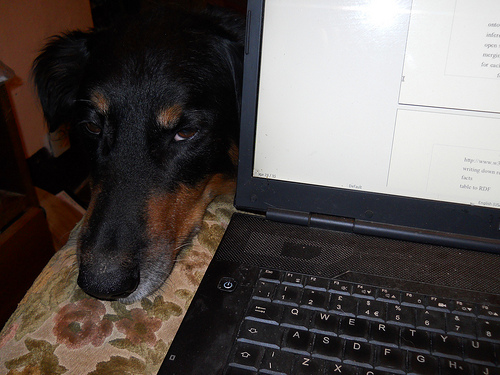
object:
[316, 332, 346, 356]
keys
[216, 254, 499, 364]
key board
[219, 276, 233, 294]
button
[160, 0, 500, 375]
laptop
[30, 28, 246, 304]
head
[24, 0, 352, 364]
dog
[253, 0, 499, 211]
screen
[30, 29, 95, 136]
ear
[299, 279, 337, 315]
key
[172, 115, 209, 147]
eye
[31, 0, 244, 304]
dog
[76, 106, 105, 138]
eye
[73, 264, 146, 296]
nose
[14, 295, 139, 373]
pattern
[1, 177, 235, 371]
chair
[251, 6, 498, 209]
light